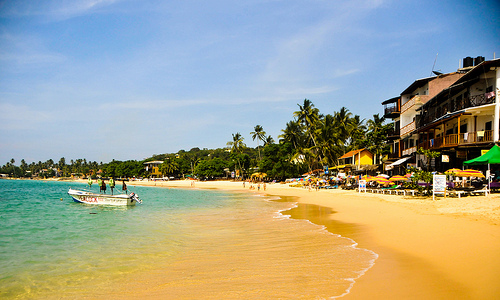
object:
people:
[302, 150, 439, 206]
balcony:
[441, 131, 489, 147]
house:
[424, 68, 498, 175]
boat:
[69, 188, 141, 209]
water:
[2, 179, 378, 299]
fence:
[356, 180, 422, 197]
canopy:
[461, 141, 499, 166]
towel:
[463, 129, 468, 140]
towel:
[476, 128, 484, 138]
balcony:
[458, 129, 493, 145]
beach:
[224, 187, 469, 290]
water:
[0, 175, 237, 280]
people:
[306, 167, 499, 197]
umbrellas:
[303, 168, 487, 182]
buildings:
[333, 57, 498, 170]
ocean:
[2, 172, 359, 298]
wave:
[245, 183, 379, 298]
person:
[95, 172, 109, 192]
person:
[105, 172, 119, 194]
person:
[117, 177, 130, 193]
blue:
[7, 183, 200, 299]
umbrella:
[464, 143, 499, 178]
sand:
[3, 176, 499, 298]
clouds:
[67, 53, 229, 138]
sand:
[395, 194, 489, 271]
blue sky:
[3, 1, 498, 159]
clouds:
[0, 78, 338, 133]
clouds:
[252, 0, 379, 82]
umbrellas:
[353, 172, 408, 184]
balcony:
[439, 127, 482, 149]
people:
[421, 122, 443, 143]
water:
[6, 186, 66, 244]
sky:
[128, 5, 264, 57]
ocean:
[8, 181, 63, 241]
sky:
[49, 17, 360, 60]